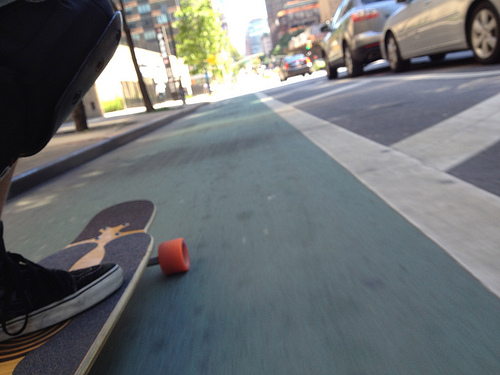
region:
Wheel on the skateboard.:
[97, 153, 208, 288]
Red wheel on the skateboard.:
[141, 225, 218, 328]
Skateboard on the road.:
[0, 207, 185, 369]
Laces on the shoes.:
[8, 249, 73, 337]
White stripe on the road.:
[298, 82, 424, 254]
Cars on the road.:
[306, 10, 448, 97]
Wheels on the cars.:
[337, 17, 439, 79]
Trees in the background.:
[168, 9, 289, 112]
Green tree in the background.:
[151, 9, 308, 114]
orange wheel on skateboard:
[153, 233, 199, 271]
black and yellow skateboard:
[0, 202, 151, 372]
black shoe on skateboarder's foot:
[2, 245, 123, 338]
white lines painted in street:
[252, 76, 495, 292]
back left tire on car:
[465, 6, 495, 56]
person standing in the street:
[198, 71, 217, 97]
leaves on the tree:
[175, 30, 195, 50]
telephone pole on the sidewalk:
[115, 25, 155, 110]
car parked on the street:
[280, 50, 315, 77]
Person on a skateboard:
[1, 188, 209, 372]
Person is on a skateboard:
[2, 194, 190, 374]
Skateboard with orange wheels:
[153, 232, 196, 286]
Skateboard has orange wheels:
[156, 230, 203, 286]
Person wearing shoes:
[0, 242, 126, 349]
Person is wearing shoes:
[0, 225, 127, 345]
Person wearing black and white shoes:
[0, 240, 130, 340]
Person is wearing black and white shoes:
[0, 220, 135, 341]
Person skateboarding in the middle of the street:
[0, 187, 201, 372]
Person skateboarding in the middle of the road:
[0, 190, 200, 372]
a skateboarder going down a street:
[7, 0, 331, 373]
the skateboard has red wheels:
[153, 233, 192, 283]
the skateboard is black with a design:
[17, 199, 153, 371]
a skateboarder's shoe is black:
[3, 234, 125, 349]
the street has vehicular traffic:
[266, 0, 499, 179]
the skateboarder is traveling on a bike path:
[8, 62, 495, 366]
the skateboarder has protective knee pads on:
[6, 1, 136, 167]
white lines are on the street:
[249, 48, 497, 248]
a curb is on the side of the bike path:
[11, 98, 213, 204]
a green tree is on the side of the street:
[163, 6, 313, 131]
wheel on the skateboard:
[158, 233, 212, 285]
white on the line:
[414, 202, 456, 246]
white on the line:
[427, 202, 473, 252]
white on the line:
[431, 136, 468, 157]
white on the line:
[356, 155, 390, 187]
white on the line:
[331, 132, 361, 158]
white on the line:
[329, 127, 354, 142]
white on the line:
[446, 125, 481, 154]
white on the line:
[326, 139, 363, 174]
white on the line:
[314, 116, 347, 143]